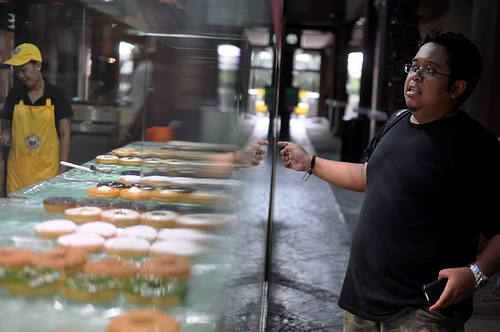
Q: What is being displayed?
A: Donuts.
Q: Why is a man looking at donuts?
A: To buy one.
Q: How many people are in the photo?
A: Two.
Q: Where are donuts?
A: Behind a glass.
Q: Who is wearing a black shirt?
A: Man on right.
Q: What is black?
A: A shirt.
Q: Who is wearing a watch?
A: The man.